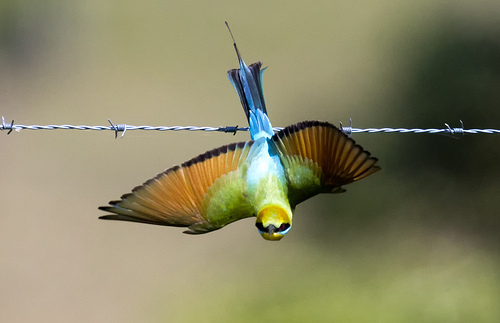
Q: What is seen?
A: Bird.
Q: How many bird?
A: 1.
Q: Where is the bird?
A: Hanging in the fence.